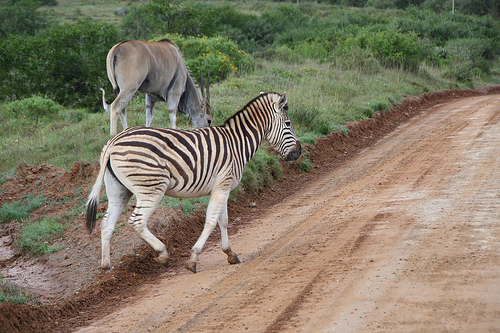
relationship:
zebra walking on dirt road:
[86, 90, 302, 275] [51, 89, 500, 331]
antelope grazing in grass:
[98, 38, 213, 137] [1, 2, 497, 293]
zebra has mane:
[86, 90, 302, 275] [220, 92, 280, 124]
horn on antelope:
[205, 71, 212, 106] [98, 38, 213, 137]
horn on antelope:
[197, 70, 205, 105] [98, 38, 213, 137]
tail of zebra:
[84, 141, 115, 234] [86, 90, 302, 275]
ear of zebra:
[275, 90, 288, 113] [86, 90, 302, 275]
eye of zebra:
[285, 121, 293, 128] [86, 90, 302, 275]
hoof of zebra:
[225, 254, 242, 267] [86, 90, 302, 275]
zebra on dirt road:
[86, 90, 302, 275] [51, 89, 500, 331]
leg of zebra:
[186, 180, 234, 273] [86, 90, 302, 275]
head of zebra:
[260, 89, 301, 166] [86, 90, 302, 275]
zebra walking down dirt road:
[86, 90, 302, 275] [51, 89, 500, 331]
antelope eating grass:
[98, 38, 213, 137] [1, 2, 497, 293]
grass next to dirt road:
[1, 2, 497, 293] [51, 89, 500, 331]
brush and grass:
[0, 118, 81, 284] [1, 2, 497, 293]